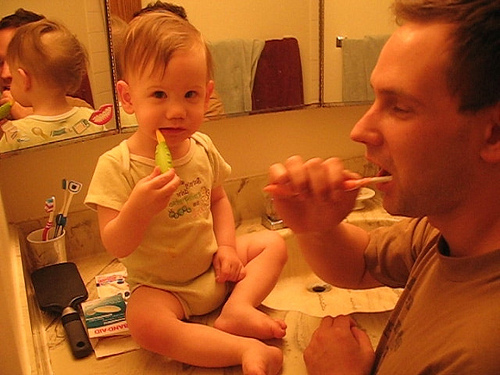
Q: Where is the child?
A: Sitting on a countertop.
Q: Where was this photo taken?
A: In a bathroom.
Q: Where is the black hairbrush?
A: On the countertop.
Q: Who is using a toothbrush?
A: The man and the baby.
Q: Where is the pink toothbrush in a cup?
A: On top of the counter.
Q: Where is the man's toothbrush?
A: In his mouth.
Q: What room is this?
A: Bathroom.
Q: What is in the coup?
A: Toothbrushes.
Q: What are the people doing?
A: Brushing teeth.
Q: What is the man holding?
A: Toothbrush.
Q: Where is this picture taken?
A: A bathroom.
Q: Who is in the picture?
A: A man and a baby.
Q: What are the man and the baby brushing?
A: Teeth.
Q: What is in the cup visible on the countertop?
A: Toothbrushes.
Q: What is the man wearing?
A: Brown tee.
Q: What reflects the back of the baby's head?
A: The mirror.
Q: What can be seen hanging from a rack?
A: Towels.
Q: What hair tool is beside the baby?
A: Brush.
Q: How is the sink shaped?
A: Like a shell.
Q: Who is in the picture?
A: A father and a baby.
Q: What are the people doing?
A: Brushing the teeth.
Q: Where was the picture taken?
A: In the bathroom.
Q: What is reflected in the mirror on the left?
A: The back of the baby's head.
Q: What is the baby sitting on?
A: The counter.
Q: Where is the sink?
A: To the right of the baby.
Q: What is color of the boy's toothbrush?
A: Lime green.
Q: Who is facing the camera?
A: The boy.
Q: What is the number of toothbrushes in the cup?
A: Three.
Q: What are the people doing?
A: Brushing teeth.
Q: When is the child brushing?
A: At the same time as dad.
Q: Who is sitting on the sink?
A: The child.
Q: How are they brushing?
A: With the toothbrush.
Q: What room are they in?
A: The bathroom.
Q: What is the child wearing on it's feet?
A: Nothing.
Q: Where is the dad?
A: In front of the child.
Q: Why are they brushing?
A: To take care of their teeth.